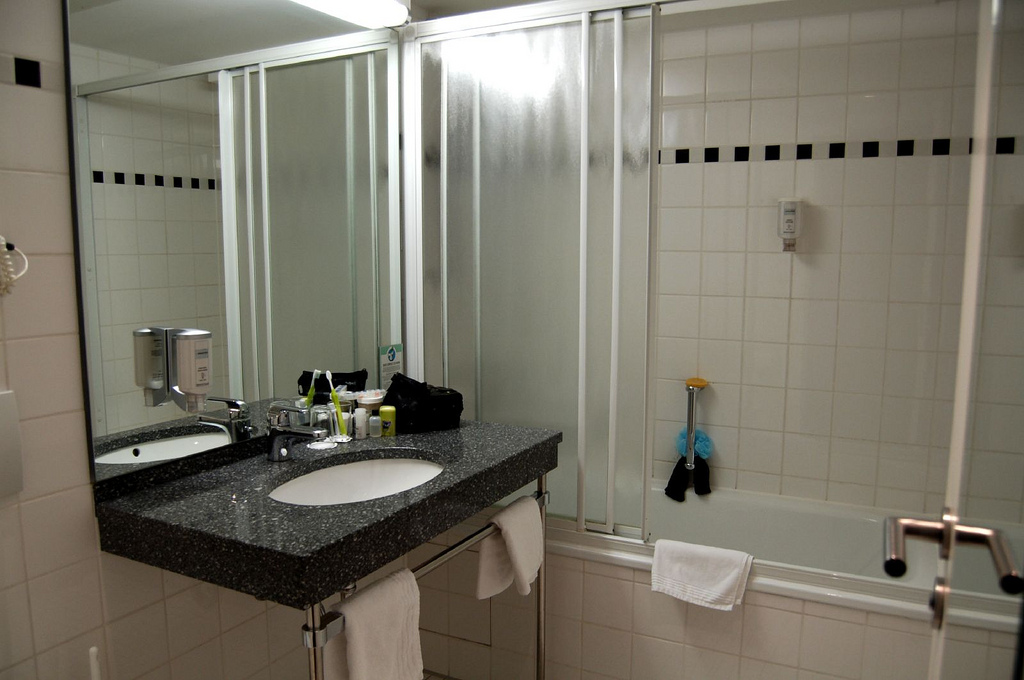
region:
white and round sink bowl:
[272, 456, 440, 499]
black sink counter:
[99, 421, 558, 603]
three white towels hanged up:
[336, 501, 748, 675]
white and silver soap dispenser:
[165, 327, 211, 411]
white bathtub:
[507, 476, 1020, 676]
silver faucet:
[266, 403, 324, 460]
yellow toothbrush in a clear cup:
[324, 369, 350, 442]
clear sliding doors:
[403, 11, 650, 530]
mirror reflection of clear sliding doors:
[71, 32, 388, 497]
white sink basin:
[275, 436, 440, 529]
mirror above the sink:
[60, 7, 414, 485]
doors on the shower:
[426, 26, 687, 533]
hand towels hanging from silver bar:
[297, 493, 542, 674]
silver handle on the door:
[872, 487, 939, 598]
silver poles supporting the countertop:
[290, 465, 551, 669]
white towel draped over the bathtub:
[651, 525, 747, 617]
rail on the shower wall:
[674, 374, 703, 466]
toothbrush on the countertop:
[315, 364, 358, 432]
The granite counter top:
[107, 392, 567, 574]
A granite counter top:
[131, 402, 562, 584]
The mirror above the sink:
[66, 54, 399, 448]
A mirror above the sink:
[46, 55, 443, 441]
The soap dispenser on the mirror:
[167, 326, 225, 396]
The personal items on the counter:
[320, 373, 407, 438]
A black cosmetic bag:
[374, 363, 464, 425]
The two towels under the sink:
[321, 502, 582, 676]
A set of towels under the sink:
[308, 491, 559, 673]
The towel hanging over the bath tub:
[637, 523, 762, 626]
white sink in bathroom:
[265, 444, 466, 568]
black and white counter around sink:
[93, 337, 539, 581]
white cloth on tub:
[667, 537, 719, 599]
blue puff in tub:
[681, 410, 710, 453]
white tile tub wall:
[613, 210, 842, 436]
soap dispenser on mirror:
[133, 322, 220, 409]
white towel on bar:
[474, 479, 554, 600]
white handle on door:
[866, 508, 959, 610]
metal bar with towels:
[403, 512, 543, 596]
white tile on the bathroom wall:
[740, 240, 798, 308]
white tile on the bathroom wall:
[737, 289, 788, 347]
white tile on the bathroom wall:
[735, 334, 784, 389]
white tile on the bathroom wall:
[725, 374, 783, 432]